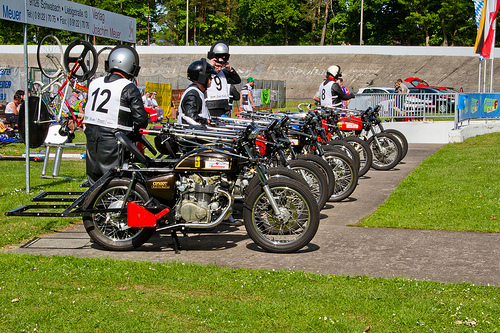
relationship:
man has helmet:
[81, 48, 148, 210] [106, 45, 140, 74]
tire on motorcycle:
[242, 173, 319, 252] [84, 129, 321, 254]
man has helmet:
[173, 58, 218, 133] [188, 58, 218, 89]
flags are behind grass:
[463, 2, 498, 89] [361, 135, 500, 229]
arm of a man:
[333, 82, 356, 103] [317, 64, 357, 109]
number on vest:
[88, 87, 111, 114] [84, 74, 138, 132]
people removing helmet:
[208, 43, 241, 115] [208, 37, 230, 67]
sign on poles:
[0, 2, 139, 43] [21, 24, 139, 194]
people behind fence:
[387, 77, 414, 113] [343, 89, 469, 128]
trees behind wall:
[3, 1, 500, 51] [4, 43, 499, 105]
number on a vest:
[88, 87, 111, 114] [84, 74, 138, 132]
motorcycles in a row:
[88, 101, 408, 252] [84, 129, 321, 254]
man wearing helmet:
[320, 64, 356, 109] [186, 59, 219, 89]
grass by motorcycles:
[3, 124, 500, 332] [88, 101, 408, 252]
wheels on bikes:
[84, 129, 408, 247] [88, 101, 408, 252]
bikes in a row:
[88, 101, 408, 252] [84, 129, 321, 254]